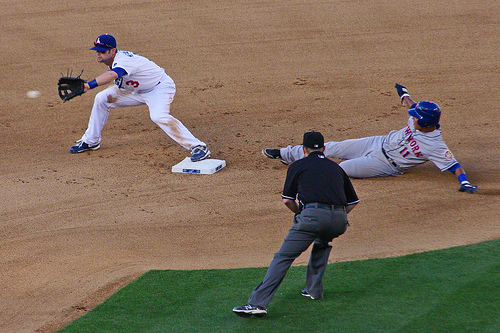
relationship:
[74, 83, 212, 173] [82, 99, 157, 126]
fielder has blue hat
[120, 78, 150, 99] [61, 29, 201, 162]
number on uniform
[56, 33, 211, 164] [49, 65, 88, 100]
fielder has glove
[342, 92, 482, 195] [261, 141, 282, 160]
runner has shoes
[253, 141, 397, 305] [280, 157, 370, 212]
umpire has shirt